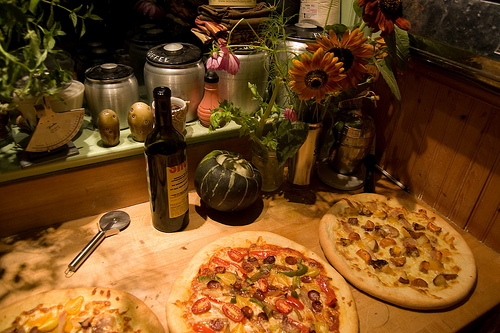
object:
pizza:
[0, 192, 478, 333]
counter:
[0, 112, 500, 333]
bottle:
[143, 86, 191, 234]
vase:
[247, 121, 376, 193]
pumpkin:
[194, 149, 263, 212]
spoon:
[64, 210, 130, 276]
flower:
[205, 0, 412, 170]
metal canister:
[82, 21, 324, 130]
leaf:
[372, 54, 403, 102]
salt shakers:
[96, 108, 120, 147]